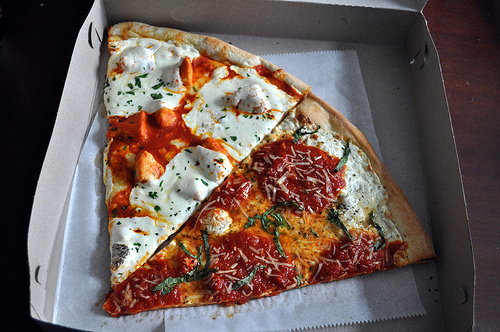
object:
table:
[0, 0, 499, 331]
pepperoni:
[210, 228, 298, 307]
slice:
[102, 96, 436, 317]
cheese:
[103, 37, 201, 120]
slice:
[104, 19, 312, 291]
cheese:
[111, 216, 169, 288]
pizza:
[100, 20, 435, 318]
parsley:
[272, 227, 289, 261]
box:
[12, 0, 478, 331]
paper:
[50, 49, 427, 331]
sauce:
[261, 141, 346, 214]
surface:
[450, 54, 500, 208]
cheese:
[183, 65, 297, 164]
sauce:
[281, 155, 326, 207]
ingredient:
[200, 230, 300, 306]